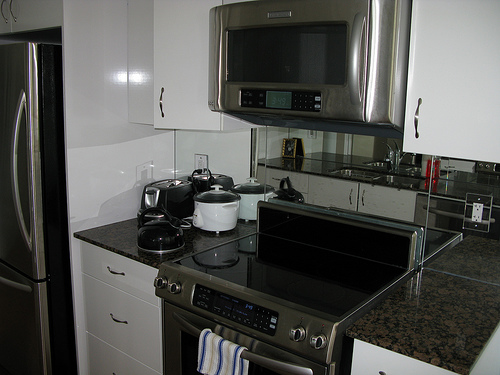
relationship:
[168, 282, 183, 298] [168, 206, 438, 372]
knob on oven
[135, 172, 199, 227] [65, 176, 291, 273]
toaster on counter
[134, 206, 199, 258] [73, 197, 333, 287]
tea kettle on counter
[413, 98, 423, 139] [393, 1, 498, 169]
handle of cabinet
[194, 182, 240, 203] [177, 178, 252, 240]
lid on crock pot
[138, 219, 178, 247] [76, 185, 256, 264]
pot sits on counter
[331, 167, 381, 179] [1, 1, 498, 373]
sink other side of kitchen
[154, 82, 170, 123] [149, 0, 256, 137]
handle of cabinet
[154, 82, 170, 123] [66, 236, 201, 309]
handle of cabinet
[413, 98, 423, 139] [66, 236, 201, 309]
handle of cabinet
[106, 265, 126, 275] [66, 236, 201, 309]
handle of cabinet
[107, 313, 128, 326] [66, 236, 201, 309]
handle of cabinet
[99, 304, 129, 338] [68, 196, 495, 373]
handle of cabinet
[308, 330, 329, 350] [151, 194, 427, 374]
knob on oven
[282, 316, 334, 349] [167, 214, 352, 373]
knob on oven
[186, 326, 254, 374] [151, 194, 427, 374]
dishtowel on oven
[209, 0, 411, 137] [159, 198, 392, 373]
microwave over stove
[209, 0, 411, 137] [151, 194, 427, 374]
microwave over oven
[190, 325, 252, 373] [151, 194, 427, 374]
towel on oven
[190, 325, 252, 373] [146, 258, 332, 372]
towel on oven door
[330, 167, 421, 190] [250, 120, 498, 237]
sink iin mirror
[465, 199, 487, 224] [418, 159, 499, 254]
outlet on wall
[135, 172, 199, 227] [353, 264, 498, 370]
toaster on counter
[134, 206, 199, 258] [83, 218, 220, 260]
tea kettle on counter